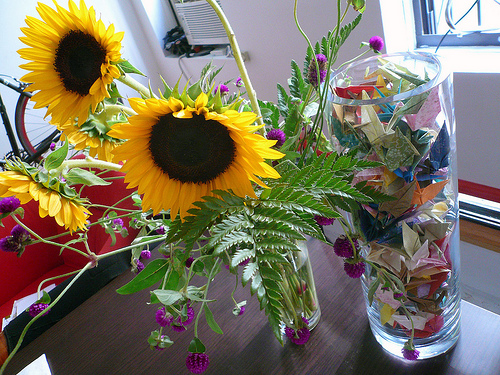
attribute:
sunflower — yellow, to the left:
[24, 3, 133, 146]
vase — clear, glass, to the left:
[220, 246, 340, 342]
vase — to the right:
[310, 57, 471, 361]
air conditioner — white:
[172, 1, 213, 57]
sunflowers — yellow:
[14, 16, 275, 239]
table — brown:
[14, 229, 354, 371]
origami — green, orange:
[363, 69, 449, 328]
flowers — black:
[15, 19, 337, 330]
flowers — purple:
[84, 204, 209, 374]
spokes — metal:
[28, 101, 55, 139]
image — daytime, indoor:
[6, 4, 495, 372]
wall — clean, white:
[242, 1, 282, 52]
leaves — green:
[178, 159, 355, 331]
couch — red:
[2, 151, 128, 306]